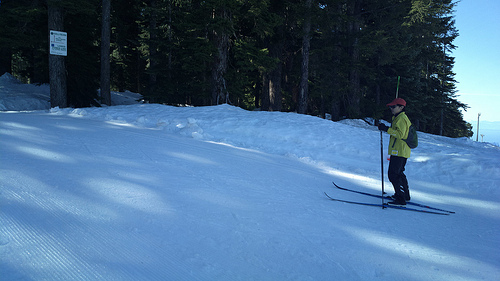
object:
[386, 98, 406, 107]
hat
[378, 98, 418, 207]
man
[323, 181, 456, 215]
black skis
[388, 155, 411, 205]
pants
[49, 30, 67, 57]
sign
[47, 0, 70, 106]
tree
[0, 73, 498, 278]
snow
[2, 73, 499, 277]
ground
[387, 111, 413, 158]
yellow jacket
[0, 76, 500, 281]
hill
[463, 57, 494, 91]
cloud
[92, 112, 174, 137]
edge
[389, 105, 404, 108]
sunglasses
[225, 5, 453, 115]
trees